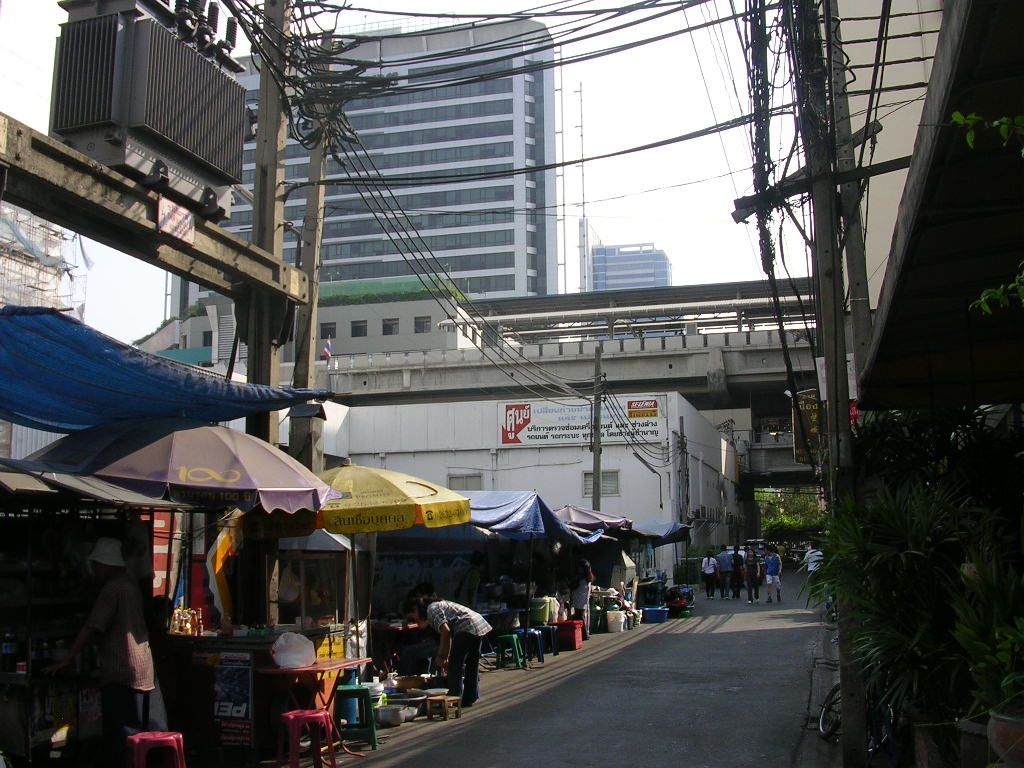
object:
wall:
[422, 35, 428, 53]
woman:
[411, 590, 494, 706]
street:
[312, 571, 840, 767]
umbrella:
[87, 427, 342, 518]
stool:
[280, 708, 335, 768]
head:
[403, 591, 428, 621]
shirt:
[424, 599, 493, 638]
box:
[425, 695, 461, 721]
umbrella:
[311, 458, 468, 536]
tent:
[451, 489, 604, 545]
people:
[699, 544, 782, 605]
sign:
[496, 399, 668, 447]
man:
[69, 540, 170, 768]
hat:
[87, 536, 128, 576]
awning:
[27, 471, 196, 510]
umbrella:
[454, 489, 604, 545]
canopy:
[318, 457, 471, 534]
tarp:
[0, 305, 332, 435]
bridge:
[328, 328, 816, 393]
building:
[347, 391, 678, 615]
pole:
[250, 72, 329, 471]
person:
[402, 592, 495, 708]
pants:
[447, 631, 483, 705]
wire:
[250, 30, 404, 165]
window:
[414, 314, 431, 333]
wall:
[317, 299, 456, 356]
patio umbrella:
[91, 425, 343, 515]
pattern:
[178, 466, 241, 484]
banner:
[499, 392, 668, 450]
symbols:
[501, 403, 533, 444]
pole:
[288, 87, 327, 475]